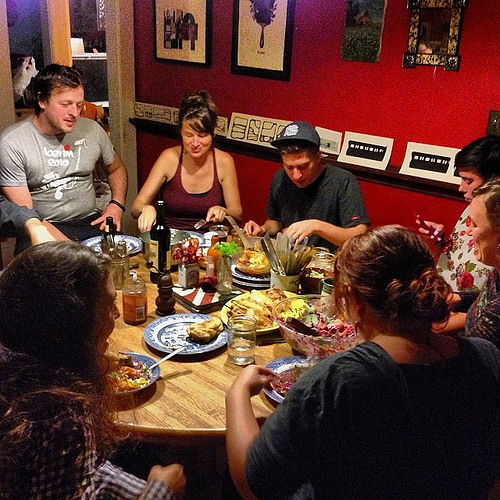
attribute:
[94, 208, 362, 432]
table — wooden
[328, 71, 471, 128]
wall — red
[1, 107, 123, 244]
t shirt — grey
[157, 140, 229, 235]
top — maroon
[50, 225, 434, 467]
table — round, wooden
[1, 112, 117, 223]
tshirt — gray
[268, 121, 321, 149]
cap — black